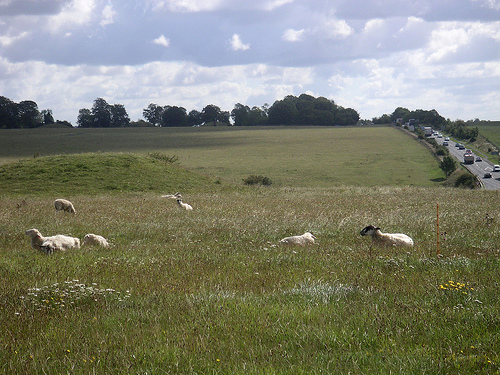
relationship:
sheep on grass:
[22, 217, 91, 267] [139, 227, 260, 333]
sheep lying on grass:
[22, 217, 91, 267] [139, 227, 260, 333]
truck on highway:
[464, 146, 480, 172] [373, 111, 495, 195]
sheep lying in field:
[352, 208, 425, 273] [127, 197, 497, 357]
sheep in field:
[352, 208, 425, 273] [127, 197, 497, 357]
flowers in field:
[434, 262, 468, 299] [127, 197, 497, 357]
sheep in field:
[31, 174, 415, 280] [127, 197, 497, 357]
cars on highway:
[425, 114, 486, 170] [373, 111, 495, 195]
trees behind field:
[2, 103, 346, 133] [127, 197, 497, 357]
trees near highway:
[2, 103, 346, 133] [373, 111, 495, 195]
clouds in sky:
[154, 5, 472, 64] [34, 4, 456, 91]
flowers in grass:
[434, 262, 468, 299] [139, 227, 260, 333]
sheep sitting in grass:
[22, 217, 91, 267] [139, 227, 260, 333]